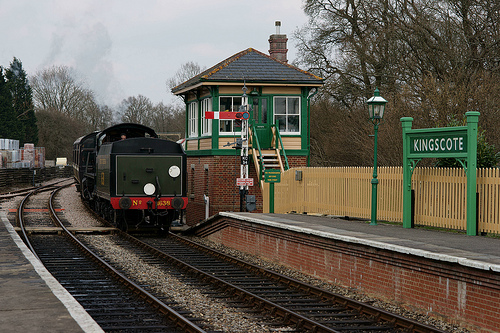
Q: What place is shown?
A: It is a train station.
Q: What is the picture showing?
A: It is showing a train station.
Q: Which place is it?
A: It is a train station.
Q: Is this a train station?
A: Yes, it is a train station.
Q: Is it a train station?
A: Yes, it is a train station.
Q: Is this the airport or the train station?
A: It is the train station.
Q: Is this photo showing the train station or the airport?
A: It is showing the train station.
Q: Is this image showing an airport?
A: No, the picture is showing a train station.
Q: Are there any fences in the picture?
A: Yes, there is a fence.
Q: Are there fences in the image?
A: Yes, there is a fence.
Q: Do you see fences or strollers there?
A: Yes, there is a fence.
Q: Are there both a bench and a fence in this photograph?
A: No, there is a fence but no benches.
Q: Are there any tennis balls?
A: No, there are no tennis balls.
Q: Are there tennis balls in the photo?
A: No, there are no tennis balls.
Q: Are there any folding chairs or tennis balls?
A: No, there are no tennis balls or folding chairs.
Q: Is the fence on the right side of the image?
A: Yes, the fence is on the right of the image.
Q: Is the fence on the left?
A: No, the fence is on the right of the image.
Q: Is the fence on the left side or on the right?
A: The fence is on the right of the image.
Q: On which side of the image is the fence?
A: The fence is on the right of the image.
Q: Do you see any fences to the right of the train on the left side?
A: Yes, there is a fence to the right of the train.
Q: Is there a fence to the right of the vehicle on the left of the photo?
A: Yes, there is a fence to the right of the train.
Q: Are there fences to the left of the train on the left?
A: No, the fence is to the right of the train.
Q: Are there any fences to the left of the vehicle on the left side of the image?
A: No, the fence is to the right of the train.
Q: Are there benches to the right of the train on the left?
A: No, there is a fence to the right of the train.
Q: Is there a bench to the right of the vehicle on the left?
A: No, there is a fence to the right of the train.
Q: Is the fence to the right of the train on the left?
A: Yes, the fence is to the right of the train.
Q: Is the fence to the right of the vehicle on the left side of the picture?
A: Yes, the fence is to the right of the train.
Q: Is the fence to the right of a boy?
A: No, the fence is to the right of the train.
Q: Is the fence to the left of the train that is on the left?
A: No, the fence is to the right of the train.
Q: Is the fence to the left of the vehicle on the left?
A: No, the fence is to the right of the train.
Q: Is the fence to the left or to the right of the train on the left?
A: The fence is to the right of the train.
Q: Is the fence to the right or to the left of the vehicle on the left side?
A: The fence is to the right of the train.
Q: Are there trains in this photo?
A: Yes, there is a train.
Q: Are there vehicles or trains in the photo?
A: Yes, there is a train.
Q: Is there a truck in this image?
A: No, there are no trucks.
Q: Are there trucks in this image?
A: No, there are no trucks.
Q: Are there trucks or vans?
A: No, there are no trucks or vans.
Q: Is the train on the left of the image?
A: Yes, the train is on the left of the image.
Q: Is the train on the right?
A: No, the train is on the left of the image.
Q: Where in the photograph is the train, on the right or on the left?
A: The train is on the left of the image.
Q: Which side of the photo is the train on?
A: The train is on the left of the image.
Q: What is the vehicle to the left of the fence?
A: The vehicle is a train.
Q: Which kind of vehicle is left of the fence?
A: The vehicle is a train.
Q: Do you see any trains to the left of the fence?
A: Yes, there is a train to the left of the fence.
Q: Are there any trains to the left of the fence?
A: Yes, there is a train to the left of the fence.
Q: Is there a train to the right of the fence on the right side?
A: No, the train is to the left of the fence.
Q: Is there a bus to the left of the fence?
A: No, there is a train to the left of the fence.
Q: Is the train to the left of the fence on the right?
A: Yes, the train is to the left of the fence.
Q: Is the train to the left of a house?
A: No, the train is to the left of the fence.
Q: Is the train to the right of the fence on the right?
A: No, the train is to the left of the fence.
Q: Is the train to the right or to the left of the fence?
A: The train is to the left of the fence.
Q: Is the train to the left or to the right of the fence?
A: The train is to the left of the fence.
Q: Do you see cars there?
A: No, there are no cars.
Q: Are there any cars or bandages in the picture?
A: No, there are no cars or bandages.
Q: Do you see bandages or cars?
A: No, there are no cars or bandages.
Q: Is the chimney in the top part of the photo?
A: Yes, the chimney is in the top of the image.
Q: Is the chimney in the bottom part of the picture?
A: No, the chimney is in the top of the image.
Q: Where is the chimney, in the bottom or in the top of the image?
A: The chimney is in the top of the image.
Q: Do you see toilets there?
A: No, there are no toilets.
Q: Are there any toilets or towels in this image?
A: No, there are no toilets or towels.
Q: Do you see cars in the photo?
A: No, there are no cars.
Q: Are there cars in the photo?
A: No, there are no cars.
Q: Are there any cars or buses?
A: No, there are no cars or buses.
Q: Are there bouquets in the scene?
A: No, there are no bouquets.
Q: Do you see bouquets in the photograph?
A: No, there are no bouquets.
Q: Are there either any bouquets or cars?
A: No, there are no bouquets or cars.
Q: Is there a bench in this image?
A: No, there are no benches.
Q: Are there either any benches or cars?
A: No, there are no benches or cars.